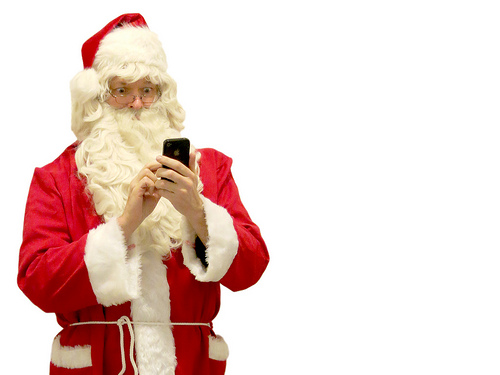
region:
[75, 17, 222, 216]
Santa Claus is texting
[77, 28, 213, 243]
Santa Claus is texting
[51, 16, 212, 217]
Santa Claus is texting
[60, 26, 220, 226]
Santa Claus is texting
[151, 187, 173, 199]
white male human finger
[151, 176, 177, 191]
white male human finger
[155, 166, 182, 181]
white male human finger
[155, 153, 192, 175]
white male human finger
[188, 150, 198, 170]
white male human finger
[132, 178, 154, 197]
white male human finger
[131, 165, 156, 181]
white male human finger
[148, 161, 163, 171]
white male human finger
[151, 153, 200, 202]
white male human fingers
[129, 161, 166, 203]
white male human fingers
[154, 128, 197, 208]
the phone is black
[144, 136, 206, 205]
the phone is black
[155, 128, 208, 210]
the phone is black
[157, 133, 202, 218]
the phone is black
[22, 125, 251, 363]
the costume is red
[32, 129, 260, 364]
the costume is red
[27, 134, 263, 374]
the costume is red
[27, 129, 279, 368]
the costume is red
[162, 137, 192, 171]
Cell phone in Santa's hand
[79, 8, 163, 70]
Red Santa Claus hat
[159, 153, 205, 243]
Hand holding a cell phone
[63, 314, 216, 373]
White string around Santa's coat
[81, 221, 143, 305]
White furry cuff on sleeve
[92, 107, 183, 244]
Long white beard on Santa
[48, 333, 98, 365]
Fur trim on pocket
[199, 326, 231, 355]
Fur trim on a pocket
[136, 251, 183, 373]
Fur trim on a coat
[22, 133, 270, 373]
Red Santa costume coat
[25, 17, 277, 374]
man dressed as santa claus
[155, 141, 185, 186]
black cellphone man is holding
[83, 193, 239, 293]
white trim on coat's cuffs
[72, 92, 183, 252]
white costume beard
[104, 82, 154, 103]
eyeglasses the man is wearing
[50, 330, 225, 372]
white trim on the coat pockets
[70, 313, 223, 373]
white rope tied around santa's waist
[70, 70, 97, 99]
white ball on the hat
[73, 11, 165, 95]
red and white santa hat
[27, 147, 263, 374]
red and white coat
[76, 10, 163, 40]
red hat on head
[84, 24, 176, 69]
white felt on hat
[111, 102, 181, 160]
long white beard on face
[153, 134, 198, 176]
black phone in Santa's hand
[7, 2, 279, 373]
Santa holds a cellphone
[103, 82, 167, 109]
glasses on the face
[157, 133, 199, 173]
cell phone is black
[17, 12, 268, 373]
santa is holding a cell phone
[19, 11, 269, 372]
santa is wearing glasses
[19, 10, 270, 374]
santa has a white beard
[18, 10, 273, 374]
santa has a red and white cap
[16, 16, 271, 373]
santa is wearing a red and white coat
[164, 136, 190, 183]
cell phone is black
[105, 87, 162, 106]
glasses are wire rimmed